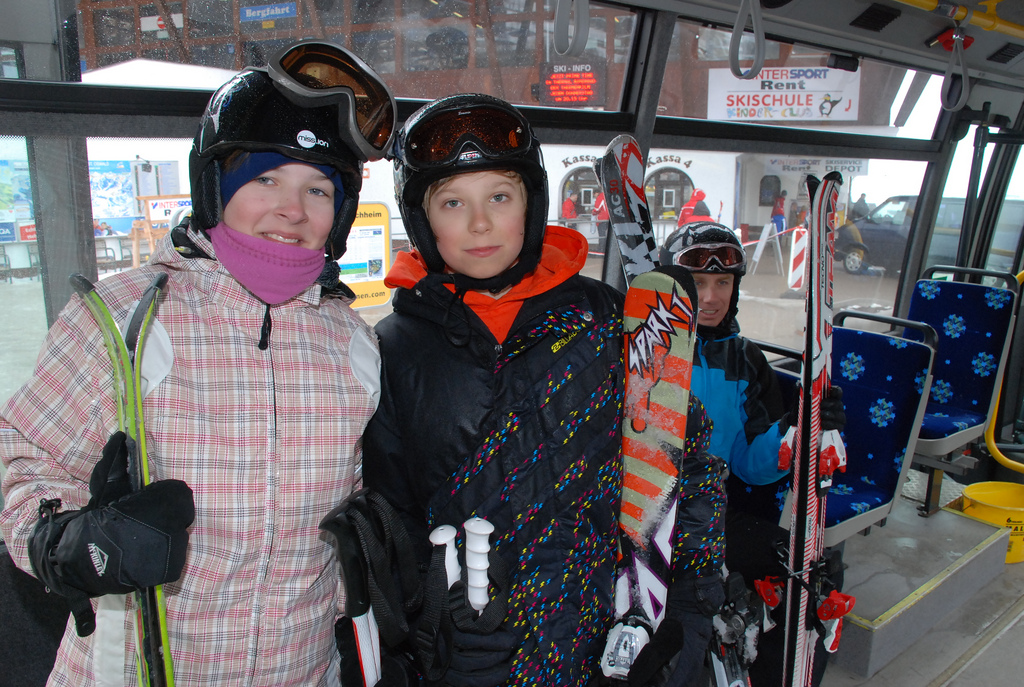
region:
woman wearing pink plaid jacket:
[1, 33, 390, 685]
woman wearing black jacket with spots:
[371, 91, 622, 683]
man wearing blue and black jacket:
[654, 218, 801, 684]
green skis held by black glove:
[34, 272, 208, 684]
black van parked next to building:
[836, 191, 1023, 277]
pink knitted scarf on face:
[205, 215, 330, 308]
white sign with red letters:
[697, 60, 869, 131]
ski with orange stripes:
[602, 262, 702, 686]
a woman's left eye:
[305, 183, 332, 200]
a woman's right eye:
[252, 173, 276, 189]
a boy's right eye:
[444, 194, 461, 205]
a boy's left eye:
[490, 192, 507, 205]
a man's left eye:
[714, 276, 731, 289]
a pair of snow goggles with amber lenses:
[403, 94, 531, 168]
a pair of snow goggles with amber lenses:
[265, 41, 396, 162]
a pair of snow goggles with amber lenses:
[669, 241, 743, 270]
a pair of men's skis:
[777, 171, 844, 684]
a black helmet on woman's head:
[393, 87, 548, 287]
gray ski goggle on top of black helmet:
[190, 37, 397, 256]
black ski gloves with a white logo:
[27, 431, 190, 635]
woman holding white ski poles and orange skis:
[364, 93, 728, 681]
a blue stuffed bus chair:
[882, 264, 1018, 520]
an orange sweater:
[384, 226, 587, 341]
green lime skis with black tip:
[73, 271, 178, 683]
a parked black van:
[830, 195, 1021, 293]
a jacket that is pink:
[14, 268, 376, 683]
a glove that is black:
[2, 464, 238, 619]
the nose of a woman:
[272, 189, 295, 232]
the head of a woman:
[201, 66, 344, 276]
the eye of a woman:
[245, 160, 350, 206]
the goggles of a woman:
[418, 104, 532, 174]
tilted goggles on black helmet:
[187, 40, 396, 260]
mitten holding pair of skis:
[30, 271, 193, 683]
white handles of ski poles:
[433, 517, 495, 606]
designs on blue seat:
[810, 309, 935, 550]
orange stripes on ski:
[611, 272, 692, 683]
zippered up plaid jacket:
[1, 234, 382, 683]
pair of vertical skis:
[775, 173, 846, 683]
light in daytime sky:
[852, 73, 1021, 201]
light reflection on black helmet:
[662, 220, 740, 277]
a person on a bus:
[134, 101, 409, 586]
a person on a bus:
[394, 113, 671, 648]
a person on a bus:
[564, 183, 862, 656]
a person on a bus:
[643, 247, 783, 674]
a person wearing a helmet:
[658, 189, 886, 569]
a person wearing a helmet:
[403, 37, 642, 449]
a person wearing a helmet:
[178, 89, 476, 659]